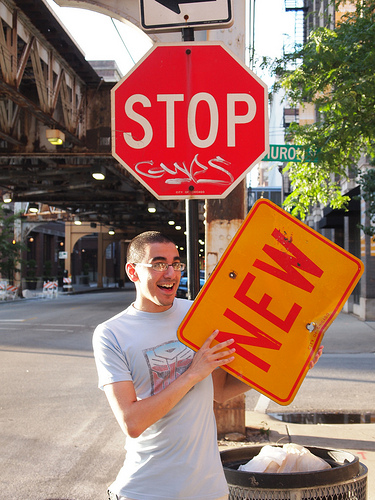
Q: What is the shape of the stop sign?
A: Octagon.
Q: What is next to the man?
A: Garbage can.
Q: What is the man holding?
A: Sign.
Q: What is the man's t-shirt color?
A: White.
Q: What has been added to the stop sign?
A: Graffiti.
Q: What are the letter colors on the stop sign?
A: White.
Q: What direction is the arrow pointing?
A: Left.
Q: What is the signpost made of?
A: Metal.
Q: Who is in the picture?
A: A man.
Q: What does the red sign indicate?
A: Stop.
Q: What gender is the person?
A: Male.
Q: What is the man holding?
A: Sign.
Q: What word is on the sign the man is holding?
A: NEW.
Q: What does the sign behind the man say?
A: STOP.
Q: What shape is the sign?
A: Octagon.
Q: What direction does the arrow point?
A: Left.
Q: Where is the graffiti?
A: On the STOP sign.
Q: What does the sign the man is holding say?
A: NEW.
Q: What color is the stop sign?
A: Red.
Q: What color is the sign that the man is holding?
A: Orange.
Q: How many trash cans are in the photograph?
A: One.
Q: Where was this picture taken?
A: A city.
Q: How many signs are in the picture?
A: Four.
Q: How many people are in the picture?
A: One.